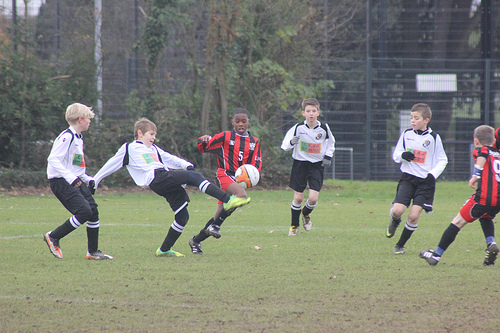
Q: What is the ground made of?
A: Grass.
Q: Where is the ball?
A: In the air.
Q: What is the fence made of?
A: Metal.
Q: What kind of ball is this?
A: Soccer ball.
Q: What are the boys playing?
A: Soccer.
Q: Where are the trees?
A: Behind the fence.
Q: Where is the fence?
A: Around the field.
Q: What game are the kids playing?
A: Soccer.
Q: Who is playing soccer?
A: Young boys.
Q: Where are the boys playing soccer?
A: Soccer field.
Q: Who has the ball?
A: Boy in orange and black at center of photo.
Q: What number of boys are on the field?
A: 6.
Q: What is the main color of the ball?
A: White.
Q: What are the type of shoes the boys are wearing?
A: Cleats.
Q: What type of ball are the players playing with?
A: Soccer.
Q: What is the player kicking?
A: Ball.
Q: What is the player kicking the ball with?
A: Foot.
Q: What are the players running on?
A: Grass.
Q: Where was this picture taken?
A: Soccer field.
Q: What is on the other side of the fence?
A: Trees.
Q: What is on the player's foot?
A: Cleats.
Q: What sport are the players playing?
A: Soccer.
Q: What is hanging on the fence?
A: Sign.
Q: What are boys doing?
A: Playing soccer.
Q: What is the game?
A: Soccer.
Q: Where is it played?
A: Soccer field.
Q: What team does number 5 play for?
A: The red with black stripes.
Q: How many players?
A: At least 7.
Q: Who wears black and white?
A: The other team.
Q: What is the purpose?
A: Score goals.